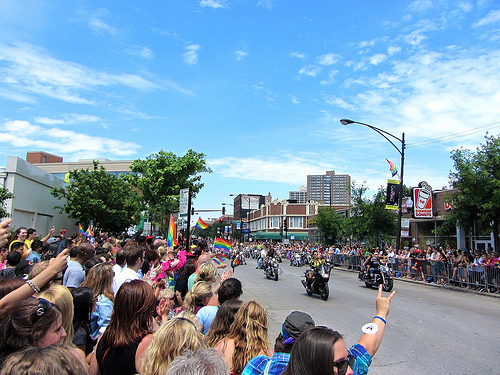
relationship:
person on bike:
[309, 247, 323, 277] [299, 261, 339, 303]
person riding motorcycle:
[307, 247, 323, 277] [299, 260, 343, 300]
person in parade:
[307, 247, 323, 277] [238, 241, 451, 323]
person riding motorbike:
[366, 250, 387, 280] [355, 260, 397, 292]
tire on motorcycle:
[319, 280, 329, 299] [300, 264, 329, 299]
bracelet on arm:
[367, 304, 391, 331] [357, 281, 395, 356]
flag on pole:
[382, 154, 398, 178] [392, 172, 402, 182]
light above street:
[219, 205, 227, 217] [241, 254, 466, 346]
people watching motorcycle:
[7, 226, 340, 374] [299, 250, 334, 300]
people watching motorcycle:
[7, 226, 340, 374] [358, 252, 395, 293]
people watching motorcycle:
[7, 226, 340, 374] [262, 245, 280, 279]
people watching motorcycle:
[7, 226, 340, 374] [234, 239, 246, 266]